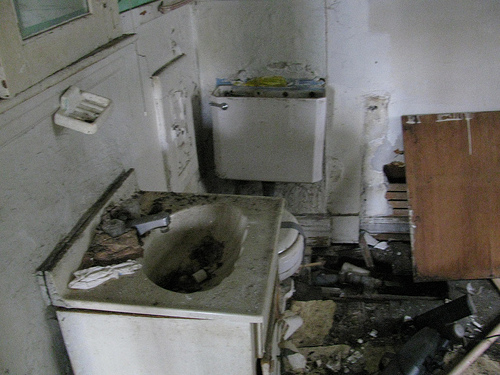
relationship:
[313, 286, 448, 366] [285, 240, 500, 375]
rubble on floor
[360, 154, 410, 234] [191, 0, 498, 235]
hole on wall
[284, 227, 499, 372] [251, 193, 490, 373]
junk on floor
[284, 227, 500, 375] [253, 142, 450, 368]
junk on floor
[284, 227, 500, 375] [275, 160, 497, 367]
junk on floor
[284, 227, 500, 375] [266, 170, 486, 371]
junk on floor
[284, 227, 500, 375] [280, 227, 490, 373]
junk on floor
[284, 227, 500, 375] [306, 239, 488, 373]
junk on floor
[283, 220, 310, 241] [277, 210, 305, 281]
tape holding toilet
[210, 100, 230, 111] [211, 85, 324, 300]
silver handle on toilet